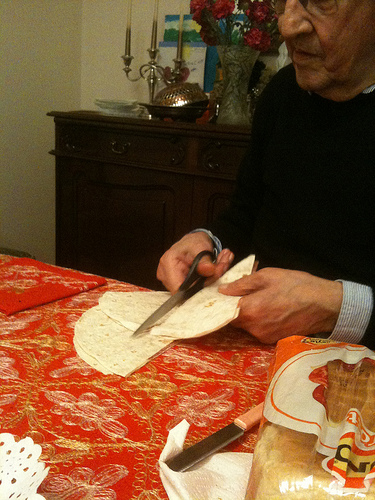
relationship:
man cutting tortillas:
[153, 4, 373, 359] [62, 268, 246, 371]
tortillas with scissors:
[64, 249, 261, 384] [127, 247, 219, 341]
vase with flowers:
[212, 41, 257, 125] [192, 1, 277, 52]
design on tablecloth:
[44, 377, 125, 450] [4, 251, 255, 499]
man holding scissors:
[156, 0, 375, 346] [128, 239, 224, 335]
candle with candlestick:
[151, 1, 158, 48] [125, 1, 131, 56]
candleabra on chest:
[116, 2, 189, 109] [39, 94, 348, 307]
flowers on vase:
[186, 0, 288, 44] [215, 46, 256, 129]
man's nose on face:
[267, 10, 310, 38] [263, 3, 363, 95]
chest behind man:
[45, 94, 348, 300] [243, 5, 351, 210]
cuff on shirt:
[324, 274, 373, 355] [239, 87, 361, 282]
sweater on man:
[198, 61, 373, 344] [153, 4, 373, 359]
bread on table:
[238, 335, 373, 498] [3, 250, 299, 498]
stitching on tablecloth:
[3, 255, 283, 498] [0, 247, 288, 499]